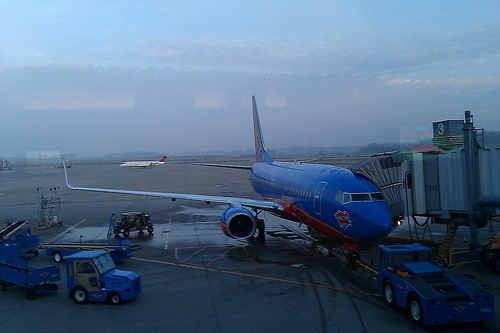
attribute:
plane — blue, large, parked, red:
[63, 93, 394, 259]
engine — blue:
[222, 206, 256, 239]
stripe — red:
[263, 196, 353, 240]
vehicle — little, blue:
[69, 250, 140, 303]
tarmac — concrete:
[6, 156, 499, 329]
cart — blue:
[382, 243, 490, 324]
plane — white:
[121, 154, 167, 167]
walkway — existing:
[354, 143, 499, 214]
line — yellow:
[132, 255, 378, 295]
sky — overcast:
[1, 0, 499, 160]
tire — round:
[73, 288, 88, 304]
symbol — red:
[336, 211, 350, 230]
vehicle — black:
[114, 212, 154, 235]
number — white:
[439, 125, 444, 135]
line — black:
[303, 265, 330, 333]